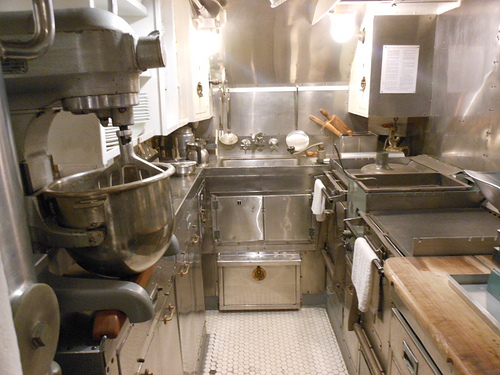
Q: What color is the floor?
A: White.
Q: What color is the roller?
A: Brown.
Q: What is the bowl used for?
A: Mixing.